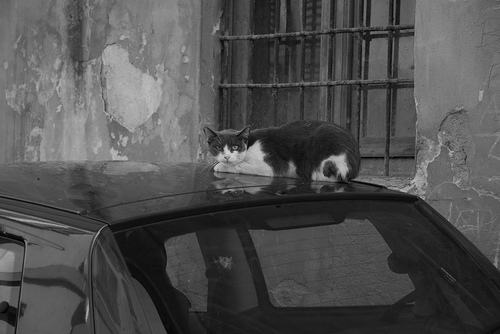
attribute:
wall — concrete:
[3, 1, 496, 307]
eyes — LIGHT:
[214, 142, 238, 151]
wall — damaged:
[6, 2, 194, 153]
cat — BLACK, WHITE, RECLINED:
[200, 121, 361, 182]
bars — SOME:
[219, 1, 416, 173]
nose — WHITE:
[211, 144, 241, 171]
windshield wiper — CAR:
[388, 204, 494, 321]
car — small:
[53, 165, 345, 300]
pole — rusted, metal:
[384, 3, 398, 180]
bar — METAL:
[213, 8, 438, 181]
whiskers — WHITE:
[232, 145, 248, 159]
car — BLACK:
[1, 150, 482, 322]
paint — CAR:
[28, 172, 118, 231]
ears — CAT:
[201, 114, 254, 146]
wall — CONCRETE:
[64, 13, 201, 148]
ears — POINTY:
[199, 118, 252, 152]